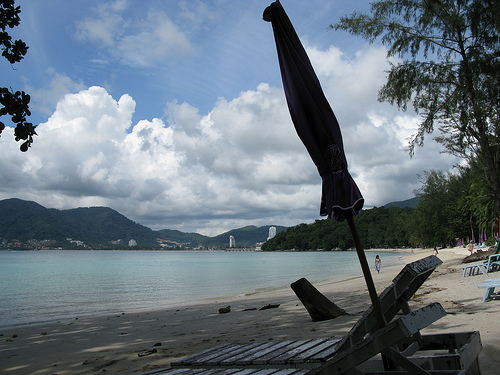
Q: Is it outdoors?
A: Yes, it is outdoors.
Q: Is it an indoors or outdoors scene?
A: It is outdoors.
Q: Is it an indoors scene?
A: No, it is outdoors.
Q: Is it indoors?
A: No, it is outdoors.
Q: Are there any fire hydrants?
A: No, there are no fire hydrants.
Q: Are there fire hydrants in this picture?
A: No, there are no fire hydrants.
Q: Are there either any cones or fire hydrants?
A: No, there are no fire hydrants or cones.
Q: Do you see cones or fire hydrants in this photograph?
A: No, there are no fire hydrants or cones.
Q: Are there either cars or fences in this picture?
A: No, there are no cars or fences.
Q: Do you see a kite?
A: No, there are no kites.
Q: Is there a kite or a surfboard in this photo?
A: No, there are no kites or surfboards.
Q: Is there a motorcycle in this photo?
A: No, there are no motorcycles.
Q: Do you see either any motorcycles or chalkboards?
A: No, there are no motorcycles or chalkboards.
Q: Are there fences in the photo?
A: No, there are no fences.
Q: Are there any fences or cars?
A: No, there are no fences or cars.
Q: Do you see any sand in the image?
A: Yes, there is sand.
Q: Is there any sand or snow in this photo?
A: Yes, there is sand.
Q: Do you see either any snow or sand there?
A: Yes, there is sand.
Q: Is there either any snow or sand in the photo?
A: Yes, there is sand.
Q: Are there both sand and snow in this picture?
A: No, there is sand but no snow.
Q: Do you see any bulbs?
A: No, there are no bulbs.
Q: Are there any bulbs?
A: No, there are no bulbs.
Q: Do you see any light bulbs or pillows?
A: No, there are no light bulbs or pillows.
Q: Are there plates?
A: Yes, there is a plate.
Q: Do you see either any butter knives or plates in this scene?
A: Yes, there is a plate.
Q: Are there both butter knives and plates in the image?
A: No, there is a plate but no butter knives.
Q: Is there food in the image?
A: No, there is no food.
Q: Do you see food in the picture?
A: No, there is no food.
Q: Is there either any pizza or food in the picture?
A: No, there are no food or pizzas.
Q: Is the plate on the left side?
A: Yes, the plate is on the left of the image.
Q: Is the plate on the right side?
A: No, the plate is on the left of the image.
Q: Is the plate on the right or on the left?
A: The plate is on the left of the image.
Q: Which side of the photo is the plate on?
A: The plate is on the left of the image.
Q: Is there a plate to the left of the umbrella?
A: Yes, there is a plate to the left of the umbrella.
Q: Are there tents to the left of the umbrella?
A: No, there is a plate to the left of the umbrella.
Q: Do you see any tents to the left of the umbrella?
A: No, there is a plate to the left of the umbrella.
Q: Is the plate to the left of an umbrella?
A: Yes, the plate is to the left of an umbrella.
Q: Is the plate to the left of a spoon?
A: No, the plate is to the left of an umbrella.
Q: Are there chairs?
A: Yes, there is a chair.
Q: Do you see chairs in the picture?
A: Yes, there is a chair.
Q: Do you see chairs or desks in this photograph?
A: Yes, there is a chair.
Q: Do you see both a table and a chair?
A: No, there is a chair but no tables.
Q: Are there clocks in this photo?
A: No, there are no clocks.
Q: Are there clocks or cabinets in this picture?
A: No, there are no clocks or cabinets.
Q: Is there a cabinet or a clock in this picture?
A: No, there are no clocks or cabinets.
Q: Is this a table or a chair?
A: This is a chair.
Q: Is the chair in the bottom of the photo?
A: Yes, the chair is in the bottom of the image.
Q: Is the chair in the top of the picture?
A: No, the chair is in the bottom of the image.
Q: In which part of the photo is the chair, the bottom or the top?
A: The chair is in the bottom of the image.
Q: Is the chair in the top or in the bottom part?
A: The chair is in the bottom of the image.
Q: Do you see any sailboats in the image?
A: No, there are no sailboats.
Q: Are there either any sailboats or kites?
A: No, there are no sailboats or kites.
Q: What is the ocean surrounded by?
A: The ocean is surrounded by the mountain.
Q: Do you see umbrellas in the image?
A: Yes, there is an umbrella.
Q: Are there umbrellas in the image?
A: Yes, there is an umbrella.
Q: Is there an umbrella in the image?
A: Yes, there is an umbrella.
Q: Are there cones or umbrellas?
A: Yes, there is an umbrella.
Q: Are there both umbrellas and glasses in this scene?
A: No, there is an umbrella but no glasses.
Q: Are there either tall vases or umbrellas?
A: Yes, there is a tall umbrella.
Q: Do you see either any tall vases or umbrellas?
A: Yes, there is a tall umbrella.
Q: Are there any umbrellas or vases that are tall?
A: Yes, the umbrella is tall.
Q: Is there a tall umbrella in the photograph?
A: Yes, there is a tall umbrella.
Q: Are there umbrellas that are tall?
A: Yes, there is an umbrella that is tall.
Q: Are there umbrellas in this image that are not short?
A: Yes, there is a tall umbrella.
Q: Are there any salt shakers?
A: No, there are no salt shakers.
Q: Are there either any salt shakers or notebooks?
A: No, there are no salt shakers or notebooks.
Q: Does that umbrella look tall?
A: Yes, the umbrella is tall.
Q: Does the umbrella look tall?
A: Yes, the umbrella is tall.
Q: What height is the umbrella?
A: The umbrella is tall.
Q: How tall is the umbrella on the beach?
A: The umbrella is tall.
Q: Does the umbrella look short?
A: No, the umbrella is tall.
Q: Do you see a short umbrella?
A: No, there is an umbrella but it is tall.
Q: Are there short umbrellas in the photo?
A: No, there is an umbrella but it is tall.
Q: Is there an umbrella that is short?
A: No, there is an umbrella but it is tall.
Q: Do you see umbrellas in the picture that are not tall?
A: No, there is an umbrella but it is tall.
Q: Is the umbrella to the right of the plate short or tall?
A: The umbrella is tall.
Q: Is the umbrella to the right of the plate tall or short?
A: The umbrella is tall.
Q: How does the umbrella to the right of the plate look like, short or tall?
A: The umbrella is tall.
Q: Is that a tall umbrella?
A: Yes, that is a tall umbrella.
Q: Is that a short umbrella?
A: No, that is a tall umbrella.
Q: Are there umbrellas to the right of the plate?
A: Yes, there is an umbrella to the right of the plate.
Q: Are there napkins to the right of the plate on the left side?
A: No, there is an umbrella to the right of the plate.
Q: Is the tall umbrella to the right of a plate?
A: Yes, the umbrella is to the right of a plate.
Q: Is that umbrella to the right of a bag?
A: No, the umbrella is to the right of a plate.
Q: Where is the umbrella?
A: The umbrella is on the beach.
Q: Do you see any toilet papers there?
A: No, there are no toilet papers.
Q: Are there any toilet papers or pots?
A: No, there are no toilet papers or pots.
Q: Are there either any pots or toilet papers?
A: No, there are no toilet papers or pots.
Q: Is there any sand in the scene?
A: Yes, there is sand.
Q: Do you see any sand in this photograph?
A: Yes, there is sand.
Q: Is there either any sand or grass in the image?
A: Yes, there is sand.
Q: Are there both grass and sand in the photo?
A: No, there is sand but no grass.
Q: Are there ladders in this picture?
A: No, there are no ladders.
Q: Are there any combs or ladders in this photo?
A: No, there are no ladders or combs.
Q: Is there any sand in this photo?
A: Yes, there is sand.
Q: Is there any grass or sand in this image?
A: Yes, there is sand.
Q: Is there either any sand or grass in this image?
A: Yes, there is sand.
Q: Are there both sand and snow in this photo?
A: No, there is sand but no snow.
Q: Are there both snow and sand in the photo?
A: No, there is sand but no snow.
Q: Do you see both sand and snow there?
A: No, there is sand but no snow.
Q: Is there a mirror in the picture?
A: No, there are no mirrors.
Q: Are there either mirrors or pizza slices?
A: No, there are no mirrors or pizza slices.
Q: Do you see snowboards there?
A: No, there are no snowboards.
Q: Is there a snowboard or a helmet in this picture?
A: No, there are no snowboards or helmets.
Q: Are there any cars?
A: No, there are no cars.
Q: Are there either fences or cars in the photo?
A: No, there are no cars or fences.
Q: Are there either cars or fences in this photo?
A: No, there are no cars or fences.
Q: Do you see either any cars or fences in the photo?
A: No, there are no cars or fences.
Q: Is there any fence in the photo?
A: No, there are no fences.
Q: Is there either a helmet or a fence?
A: No, there are no fences or helmets.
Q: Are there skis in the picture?
A: No, there are no skis.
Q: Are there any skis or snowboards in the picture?
A: No, there are no skis or snowboards.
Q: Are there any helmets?
A: No, there are no helmets.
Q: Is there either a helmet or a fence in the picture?
A: No, there are no helmets or fences.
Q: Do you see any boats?
A: No, there are no boats.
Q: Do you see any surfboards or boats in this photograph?
A: No, there are no boats or surfboards.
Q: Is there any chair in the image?
A: Yes, there is a chair.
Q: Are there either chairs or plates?
A: Yes, there is a chair.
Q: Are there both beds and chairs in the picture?
A: No, there is a chair but no beds.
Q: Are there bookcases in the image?
A: No, there are no bookcases.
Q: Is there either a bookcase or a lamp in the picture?
A: No, there are no bookcases or lamps.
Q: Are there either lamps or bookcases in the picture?
A: No, there are no bookcases or lamps.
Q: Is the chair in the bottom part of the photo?
A: Yes, the chair is in the bottom of the image.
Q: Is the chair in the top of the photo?
A: No, the chair is in the bottom of the image.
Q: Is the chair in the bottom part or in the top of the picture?
A: The chair is in the bottom of the image.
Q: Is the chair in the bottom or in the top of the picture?
A: The chair is in the bottom of the image.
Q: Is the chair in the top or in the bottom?
A: The chair is in the bottom of the image.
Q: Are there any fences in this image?
A: No, there are no fences.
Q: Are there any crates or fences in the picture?
A: No, there are no fences or crates.